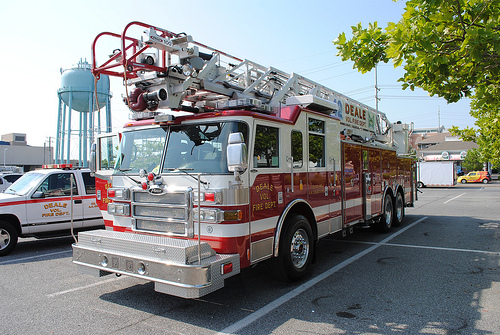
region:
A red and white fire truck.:
[83, 22, 420, 294]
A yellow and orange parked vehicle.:
[457, 171, 492, 183]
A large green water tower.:
[58, 60, 115, 169]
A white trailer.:
[417, 158, 457, 188]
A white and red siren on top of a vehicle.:
[39, 161, 73, 169]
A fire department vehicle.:
[0, 157, 126, 261]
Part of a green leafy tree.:
[329, 0, 498, 170]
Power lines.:
[298, 60, 497, 102]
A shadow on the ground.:
[98, 211, 497, 328]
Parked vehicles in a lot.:
[3, 120, 497, 333]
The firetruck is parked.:
[65, 17, 426, 302]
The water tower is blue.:
[50, 50, 115, 170]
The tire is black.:
[275, 207, 316, 287]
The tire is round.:
[270, 206, 317, 283]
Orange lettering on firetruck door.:
[246, 115, 286, 265]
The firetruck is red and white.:
[73, 17, 421, 297]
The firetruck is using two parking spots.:
[45, 23, 442, 334]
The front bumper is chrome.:
[68, 108, 251, 304]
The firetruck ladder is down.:
[70, 17, 419, 300]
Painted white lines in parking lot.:
[0, 186, 499, 333]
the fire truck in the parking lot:
[74, 15, 432, 292]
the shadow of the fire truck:
[272, 204, 499, 333]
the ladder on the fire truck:
[96, 5, 440, 150]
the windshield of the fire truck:
[116, 131, 241, 178]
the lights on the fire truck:
[82, 186, 230, 224]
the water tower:
[57, 61, 119, 171]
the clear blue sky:
[233, 16, 312, 36]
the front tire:
[256, 213, 323, 276]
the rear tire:
[374, 189, 396, 238]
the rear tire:
[390, 186, 407, 223]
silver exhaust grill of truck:
[129, 189, 191, 236]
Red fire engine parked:
[71, 55, 419, 294]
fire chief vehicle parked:
[0, 168, 100, 253]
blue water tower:
[53, 61, 112, 163]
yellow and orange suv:
[456, 168, 490, 185]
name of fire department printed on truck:
[340, 102, 372, 128]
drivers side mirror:
[222, 127, 248, 176]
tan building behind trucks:
[0, 130, 55, 170]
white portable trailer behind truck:
[418, 159, 455, 191]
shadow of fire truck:
[370, 208, 472, 334]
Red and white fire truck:
[68, 26, 427, 301]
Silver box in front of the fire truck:
[61, 216, 240, 301]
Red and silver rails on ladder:
[84, 21, 296, 111]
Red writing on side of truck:
[340, 97, 381, 142]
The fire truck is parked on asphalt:
[62, 24, 427, 302]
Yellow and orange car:
[455, 164, 492, 189]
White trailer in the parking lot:
[413, 149, 471, 205]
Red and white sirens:
[36, 152, 85, 179]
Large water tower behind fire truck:
[53, 52, 118, 166]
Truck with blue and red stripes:
[1, 160, 119, 252]